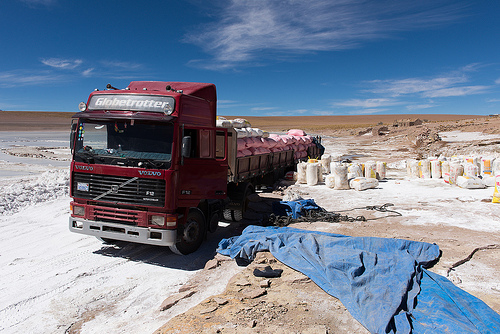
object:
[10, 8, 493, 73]
sky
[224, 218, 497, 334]
tent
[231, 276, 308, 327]
ground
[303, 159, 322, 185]
sacks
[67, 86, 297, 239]
truck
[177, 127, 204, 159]
window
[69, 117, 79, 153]
mirror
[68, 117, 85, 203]
side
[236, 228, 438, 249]
edge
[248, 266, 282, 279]
rock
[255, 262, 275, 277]
part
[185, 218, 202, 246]
rim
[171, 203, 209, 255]
wheel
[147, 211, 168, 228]
headlight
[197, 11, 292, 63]
cloud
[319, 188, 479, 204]
ground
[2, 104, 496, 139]
desert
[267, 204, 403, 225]
cord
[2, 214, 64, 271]
sand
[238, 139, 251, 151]
bags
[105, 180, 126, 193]
logo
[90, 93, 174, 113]
logo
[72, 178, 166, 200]
grill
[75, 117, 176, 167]
windshield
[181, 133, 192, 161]
mirror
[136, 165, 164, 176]
volvo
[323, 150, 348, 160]
concrete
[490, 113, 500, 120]
house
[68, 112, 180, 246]
front